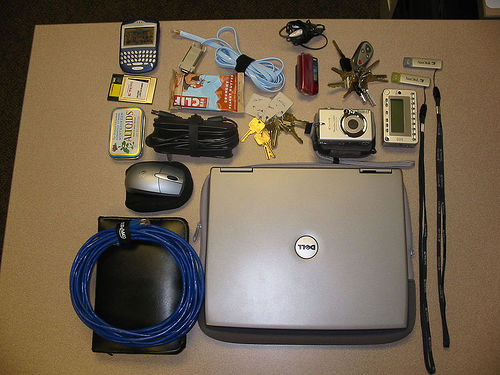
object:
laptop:
[204, 168, 408, 332]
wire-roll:
[201, 26, 285, 94]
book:
[91, 216, 190, 357]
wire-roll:
[70, 219, 206, 346]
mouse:
[125, 161, 191, 197]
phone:
[119, 17, 161, 74]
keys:
[328, 39, 389, 106]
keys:
[240, 113, 309, 160]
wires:
[145, 109, 239, 159]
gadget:
[382, 89, 420, 144]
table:
[7, 20, 499, 373]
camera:
[318, 107, 372, 145]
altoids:
[108, 107, 146, 160]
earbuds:
[279, 19, 328, 50]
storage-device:
[403, 56, 443, 69]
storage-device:
[391, 71, 430, 87]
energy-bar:
[168, 72, 245, 113]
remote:
[351, 40, 374, 68]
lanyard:
[432, 69, 451, 347]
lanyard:
[418, 87, 436, 373]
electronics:
[68, 20, 449, 375]